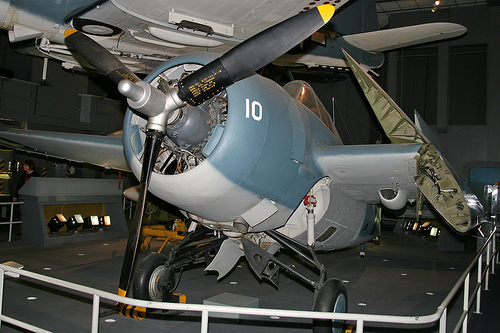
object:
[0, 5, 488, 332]
plane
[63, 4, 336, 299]
propeller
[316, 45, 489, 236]
wing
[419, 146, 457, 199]
wires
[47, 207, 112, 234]
lights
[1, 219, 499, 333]
floor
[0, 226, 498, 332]
railing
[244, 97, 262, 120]
number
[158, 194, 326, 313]
frame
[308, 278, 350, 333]
wheels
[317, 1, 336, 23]
tip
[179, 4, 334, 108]
blade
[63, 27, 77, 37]
tip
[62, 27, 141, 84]
blade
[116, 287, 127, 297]
tip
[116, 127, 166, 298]
blade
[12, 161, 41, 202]
person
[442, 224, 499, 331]
aisle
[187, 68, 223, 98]
print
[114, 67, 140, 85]
print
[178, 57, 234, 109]
base of propeller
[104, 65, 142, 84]
base of propeller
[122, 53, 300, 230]
engine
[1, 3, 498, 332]
display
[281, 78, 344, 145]
plastic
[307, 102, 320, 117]
pilot's seat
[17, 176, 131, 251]
wall